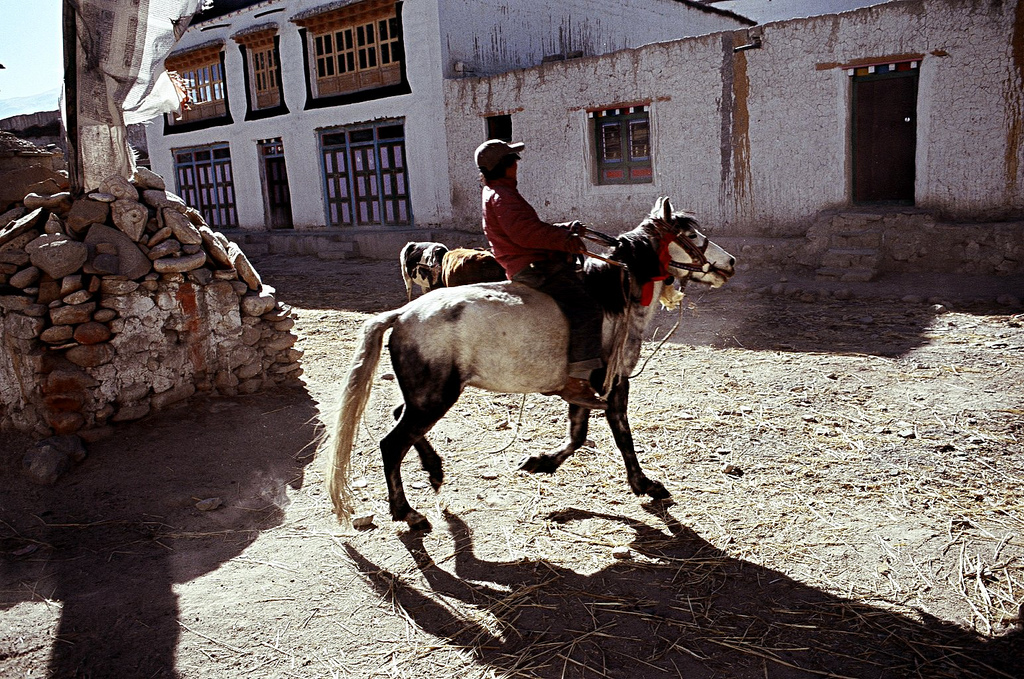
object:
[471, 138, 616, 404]
people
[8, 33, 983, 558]
outdoors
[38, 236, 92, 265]
rock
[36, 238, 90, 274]
rock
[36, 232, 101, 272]
rock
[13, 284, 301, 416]
structure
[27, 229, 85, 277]
rock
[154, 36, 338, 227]
structure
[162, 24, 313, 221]
structure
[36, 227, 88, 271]
rock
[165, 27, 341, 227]
structure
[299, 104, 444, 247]
window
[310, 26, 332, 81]
window pane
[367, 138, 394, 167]
window pane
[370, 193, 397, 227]
window pane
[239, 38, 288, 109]
window pane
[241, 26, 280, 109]
window pane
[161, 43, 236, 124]
window pane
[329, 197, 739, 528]
horse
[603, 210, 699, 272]
mane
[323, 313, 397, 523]
tail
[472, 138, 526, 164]
hat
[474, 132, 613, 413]
man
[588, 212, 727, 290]
reins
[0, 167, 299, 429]
stones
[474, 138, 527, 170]
hat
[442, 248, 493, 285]
cow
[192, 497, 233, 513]
rocks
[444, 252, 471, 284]
back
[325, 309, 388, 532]
tail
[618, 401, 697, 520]
mostly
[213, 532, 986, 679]
ground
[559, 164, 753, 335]
mostly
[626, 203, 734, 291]
head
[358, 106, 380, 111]
glass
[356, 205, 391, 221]
glass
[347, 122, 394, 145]
glass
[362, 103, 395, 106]
glass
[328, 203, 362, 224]
glass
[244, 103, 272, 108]
glass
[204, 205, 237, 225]
glass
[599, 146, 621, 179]
glass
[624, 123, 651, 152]
glass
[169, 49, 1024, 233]
building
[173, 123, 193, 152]
glass